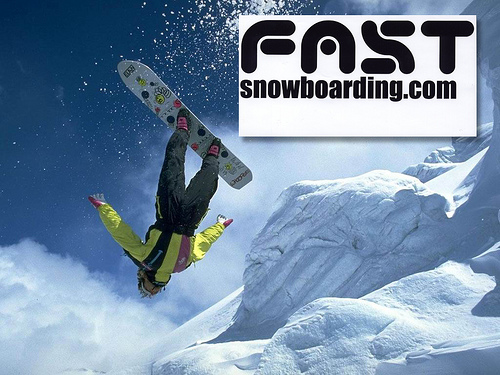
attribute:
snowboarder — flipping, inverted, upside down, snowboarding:
[87, 110, 234, 298]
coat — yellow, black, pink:
[97, 205, 225, 282]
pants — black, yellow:
[154, 128, 222, 234]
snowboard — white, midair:
[115, 60, 254, 190]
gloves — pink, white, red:
[89, 193, 235, 228]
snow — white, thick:
[140, 2, 499, 374]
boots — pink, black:
[176, 108, 220, 155]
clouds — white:
[3, 119, 498, 375]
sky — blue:
[2, 2, 495, 326]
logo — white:
[240, 18, 476, 108]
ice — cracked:
[149, 2, 495, 374]